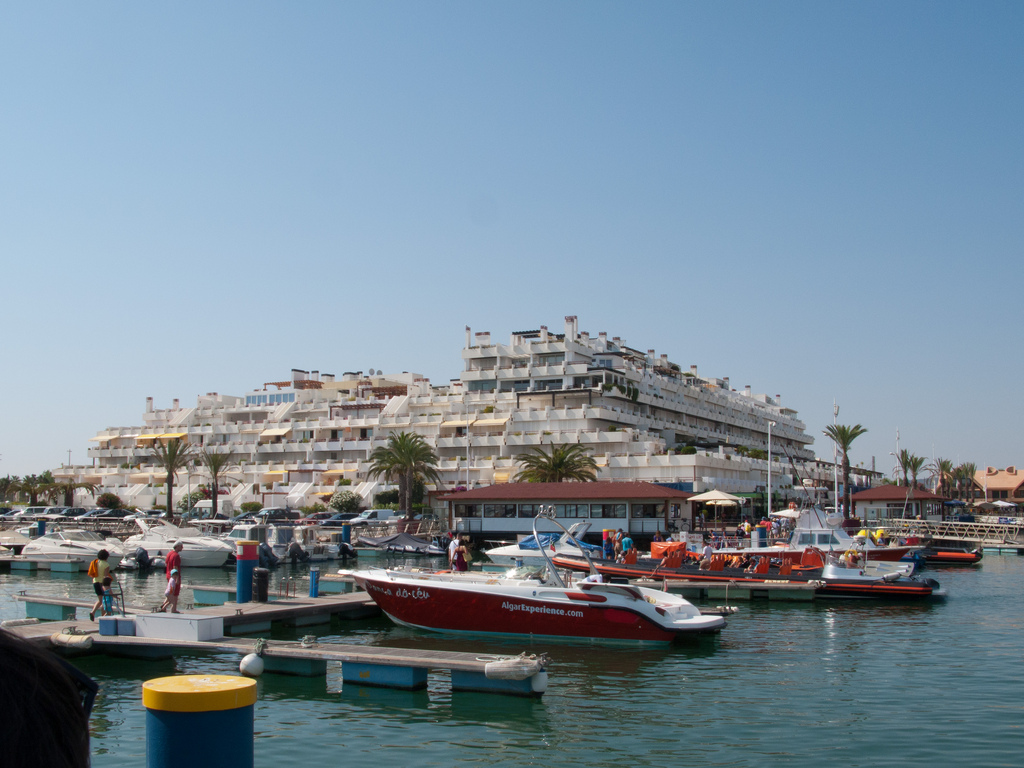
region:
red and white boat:
[336, 543, 719, 657]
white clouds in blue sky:
[321, 151, 385, 224]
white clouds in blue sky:
[207, 198, 285, 256]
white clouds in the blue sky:
[640, 156, 718, 214]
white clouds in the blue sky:
[460, 186, 538, 270]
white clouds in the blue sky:
[40, 65, 155, 165]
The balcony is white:
[447, 315, 577, 446]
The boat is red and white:
[320, 537, 786, 711]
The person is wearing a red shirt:
[124, 511, 210, 628]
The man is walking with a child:
[138, 531, 214, 611]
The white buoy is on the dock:
[106, 590, 558, 767]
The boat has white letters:
[469, 553, 707, 683]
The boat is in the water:
[315, 549, 787, 730]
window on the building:
[469, 467, 486, 478]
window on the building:
[614, 435, 657, 456]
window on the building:
[506, 345, 567, 371]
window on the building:
[346, 402, 398, 425]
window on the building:
[247, 391, 293, 411]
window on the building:
[332, 458, 375, 482]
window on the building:
[143, 464, 170, 478]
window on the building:
[288, 413, 324, 430]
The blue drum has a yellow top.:
[138, 677, 256, 764]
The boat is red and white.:
[336, 563, 720, 647]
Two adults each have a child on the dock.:
[87, 534, 189, 626]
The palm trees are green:
[150, 424, 956, 510]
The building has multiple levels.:
[50, 314, 835, 486]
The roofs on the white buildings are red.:
[441, 479, 940, 520]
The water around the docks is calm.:
[0, 553, 1022, 765]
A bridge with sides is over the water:
[881, 511, 1022, 560]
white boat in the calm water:
[330, 554, 719, 644]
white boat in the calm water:
[114, 504, 248, 566]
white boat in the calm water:
[20, 531, 131, 573]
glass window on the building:
[308, 428, 313, 452]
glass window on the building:
[454, 425, 465, 442]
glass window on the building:
[462, 378, 494, 397]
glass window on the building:
[512, 375, 531, 394]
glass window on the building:
[532, 375, 545, 392]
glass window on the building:
[563, 371, 583, 392]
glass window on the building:
[555, 373, 565, 394]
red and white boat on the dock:
[334, 537, 731, 658]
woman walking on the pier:
[73, 543, 131, 611]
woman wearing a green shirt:
[88, 560, 112, 587]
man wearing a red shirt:
[157, 547, 189, 574]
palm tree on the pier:
[822, 423, 867, 529]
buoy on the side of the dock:
[236, 638, 272, 678]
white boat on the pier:
[116, 499, 250, 573]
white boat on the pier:
[31, 519, 127, 571]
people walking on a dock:
[73, 530, 321, 622]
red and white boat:
[345, 549, 729, 658]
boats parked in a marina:
[307, 500, 974, 655]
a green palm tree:
[367, 432, 441, 530]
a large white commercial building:
[62, 319, 869, 503]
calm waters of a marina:
[545, 549, 1017, 761]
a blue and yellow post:
[137, 669, 262, 765]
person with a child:
[157, 534, 186, 618]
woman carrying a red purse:
[77, 546, 131, 626]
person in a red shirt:
[159, 538, 186, 612]